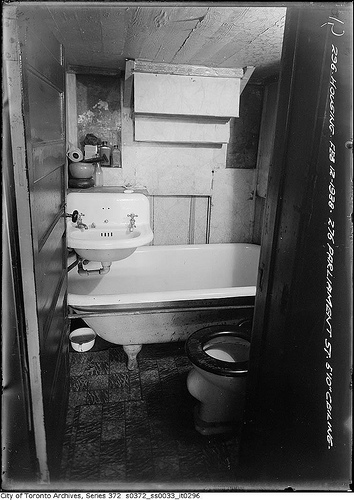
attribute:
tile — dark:
[87, 363, 107, 374]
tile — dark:
[76, 359, 88, 375]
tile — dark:
[88, 373, 106, 391]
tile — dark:
[90, 375, 109, 387]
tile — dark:
[107, 375, 126, 386]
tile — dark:
[98, 377, 116, 396]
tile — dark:
[88, 376, 107, 386]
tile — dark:
[83, 390, 109, 406]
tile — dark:
[107, 388, 124, 401]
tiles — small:
[97, 440, 164, 468]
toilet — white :
[184, 370, 239, 436]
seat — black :
[188, 323, 254, 384]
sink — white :
[67, 189, 161, 266]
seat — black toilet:
[188, 328, 262, 382]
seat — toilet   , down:
[186, 319, 260, 385]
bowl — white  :
[69, 327, 102, 355]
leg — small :
[113, 342, 153, 370]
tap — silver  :
[69, 210, 88, 222]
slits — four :
[97, 225, 116, 237]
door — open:
[7, 8, 88, 483]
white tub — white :
[54, 272, 265, 336]